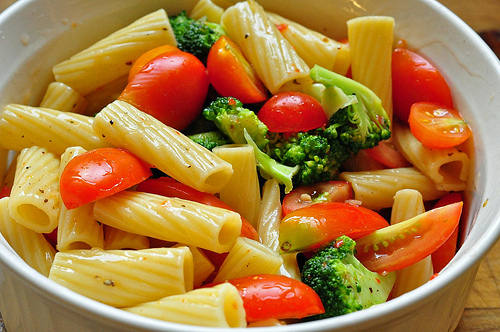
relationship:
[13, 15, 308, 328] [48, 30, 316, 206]
pasta with tomatoes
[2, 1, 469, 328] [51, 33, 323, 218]
pasta with tomatoes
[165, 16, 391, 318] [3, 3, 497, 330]
broccoli in bowl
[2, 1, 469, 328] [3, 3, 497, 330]
pasta in bowl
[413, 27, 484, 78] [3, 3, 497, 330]
sauce on bowl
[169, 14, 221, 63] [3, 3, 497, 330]
broccoli in bowl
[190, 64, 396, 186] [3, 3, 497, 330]
broccoli in bowl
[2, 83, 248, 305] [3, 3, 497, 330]
noodles in bowl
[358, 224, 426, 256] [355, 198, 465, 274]
seeds on tomato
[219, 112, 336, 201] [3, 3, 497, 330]
broccoli in middle of bowl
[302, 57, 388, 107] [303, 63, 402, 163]
stem of broccoli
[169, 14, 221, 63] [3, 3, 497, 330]
broccoli at top of bowl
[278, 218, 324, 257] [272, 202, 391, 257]
tip of tomato half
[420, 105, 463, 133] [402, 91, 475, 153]
seeds in tomato half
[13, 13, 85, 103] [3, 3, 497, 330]
dressing on side of bowl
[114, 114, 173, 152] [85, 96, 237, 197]
ridges on top of rigatoni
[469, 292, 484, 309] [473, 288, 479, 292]
spot on table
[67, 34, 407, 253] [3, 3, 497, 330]
salad in bowl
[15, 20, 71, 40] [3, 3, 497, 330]
crumbs on bowl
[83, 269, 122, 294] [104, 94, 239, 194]
seasoning on noodles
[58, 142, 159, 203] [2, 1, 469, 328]
tomato on pasta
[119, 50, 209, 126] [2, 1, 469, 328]
tomato on pasta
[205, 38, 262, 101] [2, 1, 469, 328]
tomato on pasta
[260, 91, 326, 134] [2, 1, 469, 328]
tomato on pasta